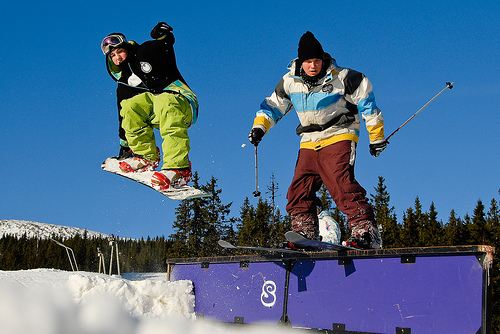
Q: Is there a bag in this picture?
A: No, there are no bags.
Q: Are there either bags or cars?
A: No, there are no bags or cars.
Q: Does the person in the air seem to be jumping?
A: Yes, the person is jumping.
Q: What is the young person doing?
A: The person is jumping.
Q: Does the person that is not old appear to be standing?
A: No, the person is jumping.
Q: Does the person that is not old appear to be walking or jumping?
A: The person is jumping.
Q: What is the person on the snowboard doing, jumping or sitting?
A: The person is jumping.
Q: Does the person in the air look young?
A: Yes, the person is young.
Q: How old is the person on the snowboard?
A: The person is young.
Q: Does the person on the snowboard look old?
A: No, the person is young.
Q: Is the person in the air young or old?
A: The person is young.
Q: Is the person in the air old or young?
A: The person is young.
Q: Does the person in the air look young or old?
A: The person is young.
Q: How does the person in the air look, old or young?
A: The person is young.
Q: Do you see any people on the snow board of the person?
A: Yes, there is a person on the snowboard.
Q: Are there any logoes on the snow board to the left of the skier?
A: No, there is a person on the snowboard.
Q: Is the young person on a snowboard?
A: Yes, the person is on a snowboard.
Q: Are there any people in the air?
A: Yes, there is a person in the air.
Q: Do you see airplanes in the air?
A: No, there is a person in the air.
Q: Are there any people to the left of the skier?
A: Yes, there is a person to the left of the skier.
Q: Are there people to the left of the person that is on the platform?
A: Yes, there is a person to the left of the skier.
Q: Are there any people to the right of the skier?
A: No, the person is to the left of the skier.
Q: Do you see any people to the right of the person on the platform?
A: No, the person is to the left of the skier.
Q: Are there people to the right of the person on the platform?
A: No, the person is to the left of the skier.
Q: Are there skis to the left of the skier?
A: No, there is a person to the left of the skier.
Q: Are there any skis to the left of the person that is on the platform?
A: No, there is a person to the left of the skier.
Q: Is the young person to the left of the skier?
A: Yes, the person is to the left of the skier.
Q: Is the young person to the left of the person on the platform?
A: Yes, the person is to the left of the skier.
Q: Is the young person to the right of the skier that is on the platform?
A: No, the person is to the left of the skier.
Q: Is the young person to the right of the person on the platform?
A: No, the person is to the left of the skier.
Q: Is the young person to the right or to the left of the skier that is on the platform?
A: The person is to the left of the skier.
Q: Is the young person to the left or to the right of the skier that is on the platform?
A: The person is to the left of the skier.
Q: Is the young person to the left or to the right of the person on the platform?
A: The person is to the left of the skier.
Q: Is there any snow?
A: Yes, there is snow.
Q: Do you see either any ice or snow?
A: Yes, there is snow.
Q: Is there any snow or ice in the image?
A: Yes, there is snow.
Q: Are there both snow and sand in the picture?
A: No, there is snow but no sand.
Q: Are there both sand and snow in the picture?
A: No, there is snow but no sand.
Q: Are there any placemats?
A: No, there are no placemats.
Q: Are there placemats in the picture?
A: No, there are no placemats.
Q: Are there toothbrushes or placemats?
A: No, there are no placemats or toothbrushes.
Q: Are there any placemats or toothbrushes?
A: No, there are no placemats or toothbrushes.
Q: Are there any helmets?
A: No, there are no helmets.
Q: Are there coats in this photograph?
A: Yes, there is a coat.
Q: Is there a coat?
A: Yes, there is a coat.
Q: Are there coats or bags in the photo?
A: Yes, there is a coat.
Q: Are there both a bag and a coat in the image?
A: No, there is a coat but no bags.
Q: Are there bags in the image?
A: No, there are no bags.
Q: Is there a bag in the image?
A: No, there are no bags.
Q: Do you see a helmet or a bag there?
A: No, there are no bags or helmets.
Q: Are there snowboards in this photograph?
A: Yes, there is a snowboard.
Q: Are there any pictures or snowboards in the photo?
A: Yes, there is a snowboard.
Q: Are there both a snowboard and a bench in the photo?
A: No, there is a snowboard but no benches.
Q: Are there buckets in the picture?
A: No, there are no buckets.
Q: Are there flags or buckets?
A: No, there are no buckets or flags.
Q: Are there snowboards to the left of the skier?
A: Yes, there is a snowboard to the left of the skier.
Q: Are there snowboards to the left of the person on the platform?
A: Yes, there is a snowboard to the left of the skier.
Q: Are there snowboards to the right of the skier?
A: No, the snowboard is to the left of the skier.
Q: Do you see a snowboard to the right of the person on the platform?
A: No, the snowboard is to the left of the skier.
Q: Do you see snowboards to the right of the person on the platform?
A: No, the snowboard is to the left of the skier.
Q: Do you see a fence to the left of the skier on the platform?
A: No, there is a snowboard to the left of the skier.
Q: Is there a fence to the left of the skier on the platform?
A: No, there is a snowboard to the left of the skier.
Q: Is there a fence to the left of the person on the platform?
A: No, there is a snowboard to the left of the skier.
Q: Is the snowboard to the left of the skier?
A: Yes, the snowboard is to the left of the skier.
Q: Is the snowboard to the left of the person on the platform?
A: Yes, the snowboard is to the left of the skier.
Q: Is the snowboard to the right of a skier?
A: No, the snowboard is to the left of a skier.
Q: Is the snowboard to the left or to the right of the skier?
A: The snowboard is to the left of the skier.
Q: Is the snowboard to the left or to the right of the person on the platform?
A: The snowboard is to the left of the skier.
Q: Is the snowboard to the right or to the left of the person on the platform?
A: The snowboard is to the left of the skier.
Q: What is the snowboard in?
A: The snowboard is in the air.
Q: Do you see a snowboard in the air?
A: Yes, there is a snowboard in the air.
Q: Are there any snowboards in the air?
A: Yes, there is a snowboard in the air.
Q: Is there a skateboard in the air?
A: No, there is a snowboard in the air.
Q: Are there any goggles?
A: Yes, there are goggles.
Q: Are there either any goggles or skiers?
A: Yes, there are goggles.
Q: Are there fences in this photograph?
A: No, there are no fences.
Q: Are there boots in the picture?
A: Yes, there are boots.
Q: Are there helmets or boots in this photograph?
A: Yes, there are boots.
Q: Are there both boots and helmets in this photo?
A: No, there are boots but no helmets.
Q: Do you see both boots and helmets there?
A: No, there are boots but no helmets.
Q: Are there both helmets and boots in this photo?
A: No, there are boots but no helmets.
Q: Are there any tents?
A: No, there are no tents.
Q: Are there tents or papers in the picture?
A: No, there are no tents or papers.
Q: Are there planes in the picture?
A: No, there are no planes.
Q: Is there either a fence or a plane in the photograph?
A: No, there are no airplanes or fences.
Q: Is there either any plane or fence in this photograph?
A: No, there are no airplanes or fences.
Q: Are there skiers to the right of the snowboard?
A: Yes, there is a skier to the right of the snowboard.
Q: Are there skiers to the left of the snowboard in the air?
A: No, the skier is to the right of the snowboard.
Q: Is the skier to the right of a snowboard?
A: Yes, the skier is to the right of a snowboard.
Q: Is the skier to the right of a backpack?
A: No, the skier is to the right of a snowboard.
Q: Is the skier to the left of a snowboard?
A: No, the skier is to the right of a snowboard.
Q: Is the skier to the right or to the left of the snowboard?
A: The skier is to the right of the snowboard.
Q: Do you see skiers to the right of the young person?
A: Yes, there is a skier to the right of the person.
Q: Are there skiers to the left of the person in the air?
A: No, the skier is to the right of the person.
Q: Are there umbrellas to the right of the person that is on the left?
A: No, there is a skier to the right of the person.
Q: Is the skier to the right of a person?
A: Yes, the skier is to the right of a person.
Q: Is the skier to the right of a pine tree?
A: No, the skier is to the right of a person.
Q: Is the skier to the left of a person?
A: No, the skier is to the right of a person.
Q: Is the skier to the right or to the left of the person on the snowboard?
A: The skier is to the right of the person.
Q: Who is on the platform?
A: The skier is on the platform.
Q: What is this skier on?
A: The skier is on the platform.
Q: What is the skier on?
A: The skier is on the platform.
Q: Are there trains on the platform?
A: No, there is a skier on the platform.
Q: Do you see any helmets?
A: No, there are no helmets.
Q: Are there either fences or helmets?
A: No, there are no helmets or fences.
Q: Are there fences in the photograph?
A: No, there are no fences.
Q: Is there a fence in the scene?
A: No, there are no fences.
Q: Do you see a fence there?
A: No, there are no fences.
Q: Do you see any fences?
A: No, there are no fences.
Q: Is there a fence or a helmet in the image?
A: No, there are no fences or helmets.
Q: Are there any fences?
A: No, there are no fences.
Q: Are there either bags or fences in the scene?
A: No, there are no fences or bags.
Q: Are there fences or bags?
A: No, there are no fences or bags.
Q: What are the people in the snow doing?
A: The people are jumping.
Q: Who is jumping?
A: The people are jumping.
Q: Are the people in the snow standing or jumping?
A: The people are jumping.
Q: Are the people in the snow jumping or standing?
A: The people are jumping.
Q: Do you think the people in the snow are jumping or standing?
A: The people are jumping.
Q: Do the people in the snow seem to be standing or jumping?
A: The people are jumping.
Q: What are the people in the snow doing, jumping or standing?
A: The people are jumping.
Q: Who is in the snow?
A: The people are in the snow.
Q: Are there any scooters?
A: No, there are no scooters.